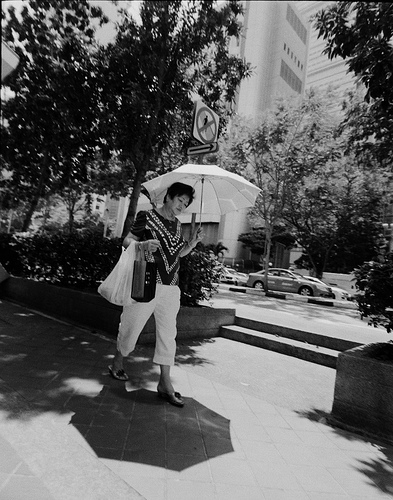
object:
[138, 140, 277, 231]
umbrella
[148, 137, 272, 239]
shadow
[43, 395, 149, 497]
ground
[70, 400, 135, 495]
lines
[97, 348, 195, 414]
shoes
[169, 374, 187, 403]
design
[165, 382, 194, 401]
flower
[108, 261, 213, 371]
cargo pants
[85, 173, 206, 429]
woman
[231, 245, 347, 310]
car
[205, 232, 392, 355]
lot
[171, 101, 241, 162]
circle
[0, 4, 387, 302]
building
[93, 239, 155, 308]
bag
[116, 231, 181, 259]
forearm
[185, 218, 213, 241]
hand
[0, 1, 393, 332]
tree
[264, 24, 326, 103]
many stories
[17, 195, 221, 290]
hedge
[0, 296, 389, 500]
street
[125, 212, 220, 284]
top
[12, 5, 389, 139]
weather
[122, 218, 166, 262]
arm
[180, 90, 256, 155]
sign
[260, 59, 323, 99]
windows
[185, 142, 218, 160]
arrow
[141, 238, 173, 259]
wrist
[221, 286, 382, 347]
sidewalk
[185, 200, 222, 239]
post